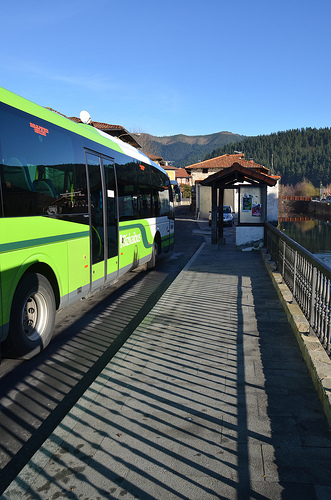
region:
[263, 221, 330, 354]
black iron rails at edge of road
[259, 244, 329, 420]
Stone base for iron bars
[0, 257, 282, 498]
shadow of iron bars on ground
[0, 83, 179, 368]
green and white bus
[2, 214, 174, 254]
dark green stripe on light green background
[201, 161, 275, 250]
bus stop shelter with green posts and red roof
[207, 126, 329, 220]
lush trees in right distance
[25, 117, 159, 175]
orange lights on black surface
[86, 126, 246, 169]
view of mountains in middle distance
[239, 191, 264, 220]
flyers on bus stop billboard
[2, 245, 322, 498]
a sidewalk alongside a road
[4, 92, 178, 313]
a green and white bus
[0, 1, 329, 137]
a beautiful blue sky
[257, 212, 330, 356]
railing next to water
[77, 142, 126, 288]
a double door on a bus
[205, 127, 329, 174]
a pine tree covered hill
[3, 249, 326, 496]
the shadow of the railing on the sidewalk and road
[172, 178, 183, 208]
the sideview mirror on a bus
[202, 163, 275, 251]
a covered bus stop next to the road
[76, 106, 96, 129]
a satellite dish on a roof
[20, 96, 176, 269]
The bus is parked.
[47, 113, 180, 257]
The bus is green.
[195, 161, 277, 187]
The roof of the bus stop is brick.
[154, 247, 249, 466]
The sidewalk has shadow of railing.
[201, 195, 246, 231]
A car parked next to the building.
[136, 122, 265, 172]
The mountains in the background.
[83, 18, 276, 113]
The sky is blue and clear.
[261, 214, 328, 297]
A railing across the bridge.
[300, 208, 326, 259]
Water on the side of the bridge.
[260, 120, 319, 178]
The trees are tall and green.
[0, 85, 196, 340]
Long green bus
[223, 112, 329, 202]
Trees on a hill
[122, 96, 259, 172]
Mountains in the distance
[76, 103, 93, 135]
Satellite dish on top of a roof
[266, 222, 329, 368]
Rail at a bus stop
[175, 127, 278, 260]
Bus stop pavillion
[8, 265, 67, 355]
Tire on a green bus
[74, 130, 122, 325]
Doors on a bus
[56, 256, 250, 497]
Shadow of a rail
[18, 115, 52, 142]
Orange letters on bus window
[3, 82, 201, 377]
lime green colored city bus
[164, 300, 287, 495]
gray cement tile sidewalk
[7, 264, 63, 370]
large black rubber tire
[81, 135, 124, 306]
lime green and tinted glass bus door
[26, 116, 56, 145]
orange lighted bus destination sign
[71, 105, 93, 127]
large white satelite dish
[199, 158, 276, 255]
open bus shelter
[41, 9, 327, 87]
clear cloudless blue sky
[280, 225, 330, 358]
decorative bridge railing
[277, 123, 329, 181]
mountain with thick evergreen trees